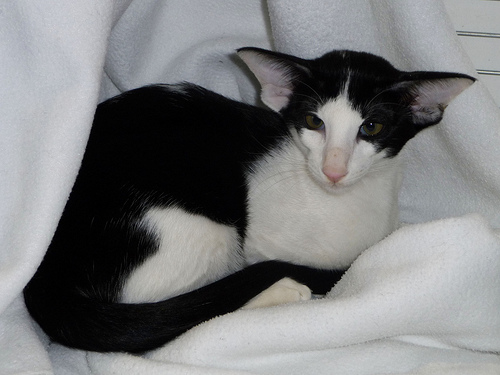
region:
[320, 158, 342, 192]
Cat has pink nose.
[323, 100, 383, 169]
White fur on cat's face.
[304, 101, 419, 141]
Cat has light eyes.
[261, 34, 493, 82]
Cat has black ears.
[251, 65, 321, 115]
Inside of cat's ears are pink.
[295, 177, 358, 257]
Cat has white fur on neck.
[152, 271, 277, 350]
Cat has black tail.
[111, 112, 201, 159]
Cat has black fur on back.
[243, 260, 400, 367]
Cat is laying on white towel.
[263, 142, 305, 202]
Cat has white whiskers.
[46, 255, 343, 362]
tail of the cat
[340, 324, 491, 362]
wrinkle in the blanket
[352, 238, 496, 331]
blanket cat is on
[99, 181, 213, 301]
spot on the cat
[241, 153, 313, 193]
whiskers on the cat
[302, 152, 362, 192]
nose of the cat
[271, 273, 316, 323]
foot of the cat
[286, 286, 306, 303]
toe of the cat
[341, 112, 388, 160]
eye of the cat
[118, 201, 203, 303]
fur on the cat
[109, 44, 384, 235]
the cat is black and white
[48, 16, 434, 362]
the cat is black and white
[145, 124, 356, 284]
the cat is black and white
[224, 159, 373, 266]
the cat is black and white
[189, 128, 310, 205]
the cat is black and white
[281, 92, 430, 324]
the cat is black and white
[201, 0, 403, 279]
the cat is black and white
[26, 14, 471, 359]
a cat lying in the turkey towel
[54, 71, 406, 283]
a black and white colour cat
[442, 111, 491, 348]
a white colour turkey towel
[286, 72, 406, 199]
a pink colour nose with mustache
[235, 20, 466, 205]
a face of the cat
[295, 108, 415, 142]
brownish eyes of the cat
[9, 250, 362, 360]
a tail of the cat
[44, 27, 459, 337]
a cat focusing on the photographer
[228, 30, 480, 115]
ear of the cat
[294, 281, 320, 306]
nail of the cat